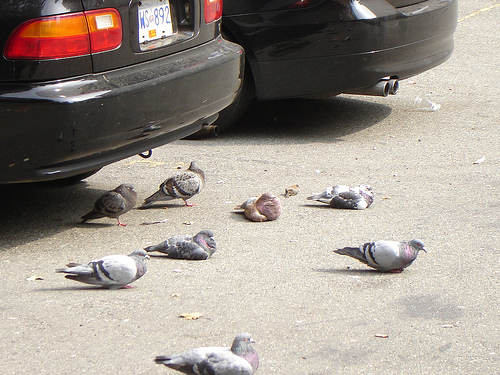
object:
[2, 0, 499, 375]
road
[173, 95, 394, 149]
shadow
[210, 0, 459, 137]
car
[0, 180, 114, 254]
shadow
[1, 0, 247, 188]
car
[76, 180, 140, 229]
pigeon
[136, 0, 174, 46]
licence plate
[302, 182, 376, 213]
pigeon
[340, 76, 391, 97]
twin mufflers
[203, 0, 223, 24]
light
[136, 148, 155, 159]
tow hitch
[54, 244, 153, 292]
pigeon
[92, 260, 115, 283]
stripes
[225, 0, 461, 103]
bumper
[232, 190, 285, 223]
bird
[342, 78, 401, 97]
dual exhaust pipes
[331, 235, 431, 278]
pigeon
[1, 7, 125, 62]
light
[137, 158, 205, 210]
birds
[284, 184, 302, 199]
leaf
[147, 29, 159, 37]
sticker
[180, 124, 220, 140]
exhaust pipe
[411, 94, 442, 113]
cup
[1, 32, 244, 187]
bumper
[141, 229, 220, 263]
pigeon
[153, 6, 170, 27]
892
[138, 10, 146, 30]
letter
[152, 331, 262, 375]
pigeon